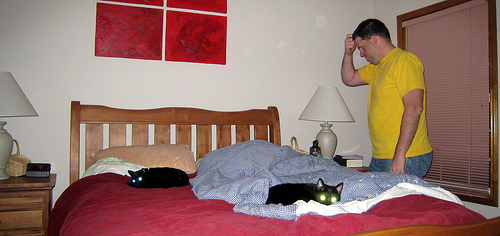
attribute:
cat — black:
[265, 178, 344, 206]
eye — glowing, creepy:
[320, 195, 325, 201]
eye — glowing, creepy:
[331, 197, 336, 202]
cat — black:
[127, 167, 189, 190]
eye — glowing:
[139, 177, 143, 181]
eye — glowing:
[132, 179, 136, 183]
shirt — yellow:
[358, 46, 433, 159]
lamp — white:
[0, 71, 38, 180]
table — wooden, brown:
[0, 174, 56, 236]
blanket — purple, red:
[46, 170, 488, 235]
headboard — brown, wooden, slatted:
[70, 100, 282, 185]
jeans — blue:
[368, 152, 434, 179]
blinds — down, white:
[401, 0, 489, 200]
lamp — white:
[299, 87, 356, 160]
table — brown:
[347, 165, 370, 172]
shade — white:
[0, 72, 39, 117]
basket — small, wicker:
[4, 139, 31, 177]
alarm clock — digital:
[26, 163, 51, 178]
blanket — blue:
[188, 139, 464, 221]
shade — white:
[298, 86, 355, 122]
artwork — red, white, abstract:
[93, 0, 229, 67]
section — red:
[94, 2, 165, 61]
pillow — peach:
[92, 144, 197, 174]